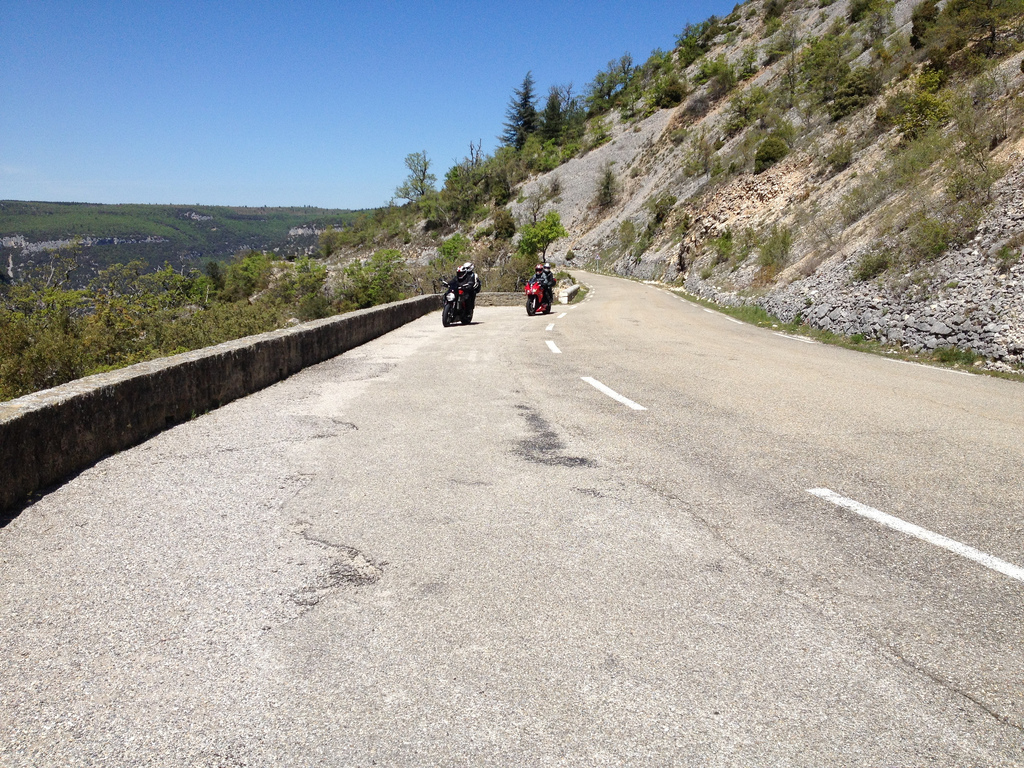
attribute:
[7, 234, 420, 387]
plants — green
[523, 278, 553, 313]
motorcycle — red, black 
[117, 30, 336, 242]
sky — clear, Blue